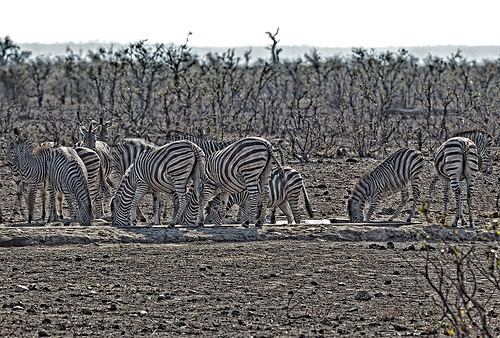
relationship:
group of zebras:
[13, 120, 485, 242] [13, 128, 323, 220]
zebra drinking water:
[342, 139, 427, 236] [334, 213, 404, 227]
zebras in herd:
[13, 128, 323, 220] [13, 120, 485, 242]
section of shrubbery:
[267, 60, 397, 130] [278, 58, 371, 128]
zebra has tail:
[342, 139, 427, 236] [416, 147, 430, 184]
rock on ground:
[353, 288, 372, 303] [166, 259, 423, 320]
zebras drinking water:
[13, 128, 323, 220] [334, 213, 404, 227]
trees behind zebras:
[76, 42, 358, 119] [13, 128, 323, 220]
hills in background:
[200, 40, 270, 54] [0, 0, 480, 92]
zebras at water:
[13, 128, 323, 220] [334, 213, 404, 227]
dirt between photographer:
[40, 245, 420, 325] [352, 318, 444, 333]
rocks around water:
[4, 221, 307, 240] [334, 213, 404, 227]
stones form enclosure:
[67, 223, 238, 242] [2, 225, 483, 238]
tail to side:
[416, 147, 430, 184] [403, 150, 434, 210]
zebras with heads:
[0, 115, 117, 175] [1, 120, 110, 149]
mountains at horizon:
[24, 6, 495, 56] [15, 1, 488, 49]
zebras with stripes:
[13, 128, 323, 220] [215, 145, 259, 178]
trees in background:
[76, 42, 358, 119] [0, 0, 480, 92]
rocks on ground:
[156, 251, 347, 289] [166, 259, 423, 320]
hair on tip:
[295, 198, 319, 220] [304, 203, 318, 213]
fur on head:
[10, 124, 23, 144] [0, 127, 36, 178]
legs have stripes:
[124, 181, 190, 229] [170, 180, 185, 220]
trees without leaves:
[76, 42, 358, 119] [244, 71, 277, 104]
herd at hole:
[13, 120, 485, 242] [75, 209, 429, 244]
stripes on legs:
[215, 145, 259, 178] [235, 135, 269, 201]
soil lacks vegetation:
[123, 241, 336, 312] [406, 265, 499, 337]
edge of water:
[324, 223, 368, 241] [334, 213, 404, 227]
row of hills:
[419, 41, 447, 57] [200, 40, 270, 54]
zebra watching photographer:
[0, 137, 55, 226] [352, 318, 444, 333]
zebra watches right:
[432, 124, 498, 228] [347, 70, 497, 240]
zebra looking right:
[432, 124, 498, 228] [418, 45, 498, 325]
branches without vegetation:
[278, 58, 371, 128] [3, 29, 499, 136]